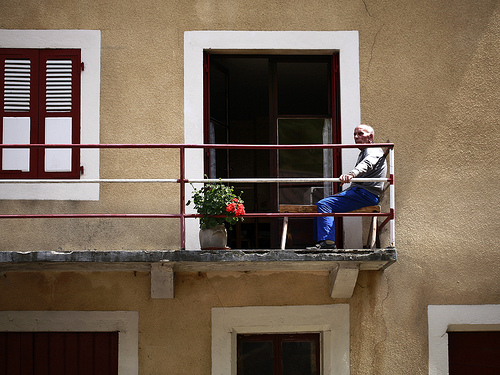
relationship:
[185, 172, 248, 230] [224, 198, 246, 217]
plant with flowers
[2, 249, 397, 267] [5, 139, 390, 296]
floor of balcony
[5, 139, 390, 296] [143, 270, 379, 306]
balcony with supports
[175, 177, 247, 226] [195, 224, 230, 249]
plant in a pot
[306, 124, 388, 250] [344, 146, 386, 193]
man wearing jacket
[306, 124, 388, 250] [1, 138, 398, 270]
man on balcony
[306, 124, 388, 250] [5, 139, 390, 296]
man sitting on balcony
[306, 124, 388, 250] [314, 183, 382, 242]
man wearing blue jeans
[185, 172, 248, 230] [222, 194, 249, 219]
plant has red flower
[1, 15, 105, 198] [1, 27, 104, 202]
window has frame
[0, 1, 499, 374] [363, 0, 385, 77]
wall has crack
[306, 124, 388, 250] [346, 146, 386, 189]
man in shirt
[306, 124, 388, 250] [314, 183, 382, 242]
man in blue jeans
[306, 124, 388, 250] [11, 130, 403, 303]
man in patio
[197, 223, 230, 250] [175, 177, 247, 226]
pot in plant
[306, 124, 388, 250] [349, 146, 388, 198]
man in jacket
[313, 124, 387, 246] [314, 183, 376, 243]
man in blue jeans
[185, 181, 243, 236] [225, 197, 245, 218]
green leaves in flower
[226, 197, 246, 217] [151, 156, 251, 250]
flower on plant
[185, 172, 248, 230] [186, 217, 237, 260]
plant in pot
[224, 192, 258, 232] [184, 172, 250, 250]
flower in a pot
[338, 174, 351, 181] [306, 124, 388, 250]
hand of a man